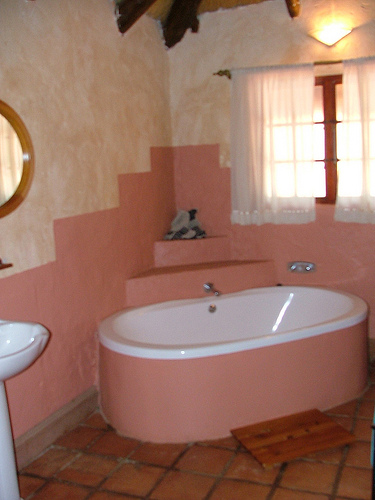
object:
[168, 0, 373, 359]
wall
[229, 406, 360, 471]
board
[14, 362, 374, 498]
floor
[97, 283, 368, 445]
bathtub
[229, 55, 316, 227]
curtain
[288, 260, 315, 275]
knobs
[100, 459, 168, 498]
tiles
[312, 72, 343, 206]
frame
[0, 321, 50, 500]
sink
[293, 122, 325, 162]
light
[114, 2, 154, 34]
beams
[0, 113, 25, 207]
mirror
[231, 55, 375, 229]
curtains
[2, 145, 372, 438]
enclosure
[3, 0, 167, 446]
wall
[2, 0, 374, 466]
walls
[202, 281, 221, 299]
faucet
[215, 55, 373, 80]
rod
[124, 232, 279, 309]
shelf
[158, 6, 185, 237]
corner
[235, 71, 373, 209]
window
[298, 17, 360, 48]
light fixture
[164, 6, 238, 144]
wall